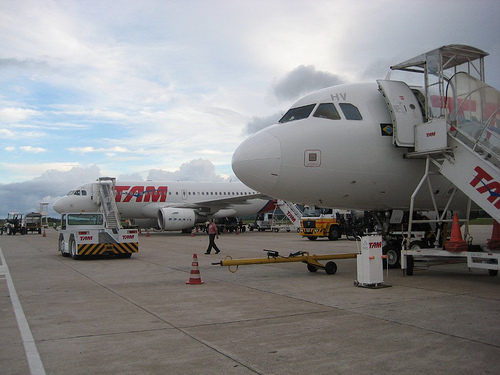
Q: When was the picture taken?
A: Daytime.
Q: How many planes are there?
A: Two.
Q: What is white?
A: Planes.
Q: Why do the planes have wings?
A: To fly.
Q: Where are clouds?
A: In the sky.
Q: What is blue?
A: Sky.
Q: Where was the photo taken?
A: At the airport.